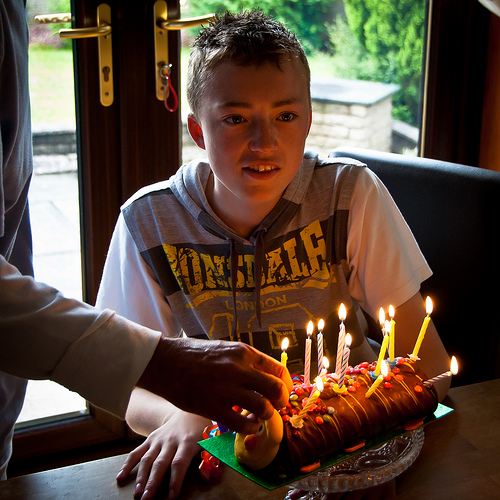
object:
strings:
[253, 230, 267, 330]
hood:
[169, 149, 321, 248]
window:
[13, 0, 86, 427]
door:
[112, 0, 491, 443]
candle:
[303, 319, 315, 384]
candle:
[334, 301, 348, 375]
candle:
[318, 354, 330, 382]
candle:
[280, 335, 292, 369]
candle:
[372, 321, 395, 377]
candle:
[386, 301, 397, 367]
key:
[158, 60, 181, 113]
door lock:
[99, 63, 112, 83]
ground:
[0, 144, 85, 420]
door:
[0, 0, 130, 472]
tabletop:
[0, 378, 499, 499]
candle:
[316, 316, 326, 377]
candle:
[337, 331, 353, 393]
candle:
[406, 293, 433, 360]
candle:
[418, 354, 460, 387]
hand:
[158, 332, 292, 436]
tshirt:
[94, 152, 437, 385]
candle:
[290, 379, 326, 427]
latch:
[156, 59, 173, 100]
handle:
[58, 3, 116, 109]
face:
[182, 7, 314, 204]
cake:
[229, 355, 440, 475]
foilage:
[381, 80, 425, 143]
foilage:
[398, 1, 428, 42]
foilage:
[363, 1, 391, 53]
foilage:
[285, 1, 339, 53]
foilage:
[172, 0, 290, 34]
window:
[177, 0, 430, 167]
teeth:
[259, 162, 266, 173]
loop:
[162, 74, 178, 112]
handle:
[153, 0, 217, 104]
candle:
[377, 305, 388, 337]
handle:
[57, 22, 114, 43]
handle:
[157, 12, 221, 34]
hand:
[113, 409, 215, 500]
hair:
[183, 10, 314, 118]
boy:
[84, 9, 454, 500]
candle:
[364, 358, 394, 399]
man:
[0, 0, 296, 500]